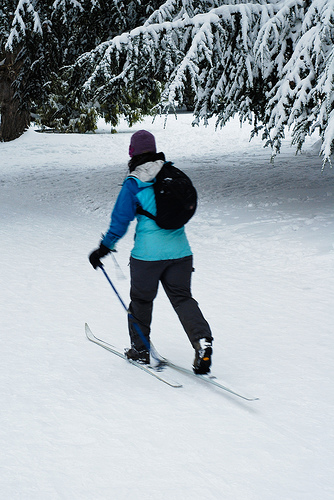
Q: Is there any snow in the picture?
A: Yes, there is snow.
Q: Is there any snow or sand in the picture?
A: Yes, there is snow.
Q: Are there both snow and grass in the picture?
A: No, there is snow but no grass.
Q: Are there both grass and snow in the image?
A: No, there is snow but no grass.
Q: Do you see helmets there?
A: No, there are no helmets.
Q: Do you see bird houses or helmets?
A: No, there are no helmets or bird houses.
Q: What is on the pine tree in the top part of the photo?
A: The snow is on the pine.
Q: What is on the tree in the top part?
A: The snow is on the pine.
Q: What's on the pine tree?
A: The snow is on the pine.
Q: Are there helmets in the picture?
A: No, there are no helmets.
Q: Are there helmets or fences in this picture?
A: No, there are no helmets or fences.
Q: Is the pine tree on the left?
A: Yes, the pine tree is on the left of the image.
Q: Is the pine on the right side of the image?
A: No, the pine is on the left of the image.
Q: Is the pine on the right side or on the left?
A: The pine is on the left of the image.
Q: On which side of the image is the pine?
A: The pine is on the left of the image.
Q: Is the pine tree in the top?
A: Yes, the pine tree is in the top of the image.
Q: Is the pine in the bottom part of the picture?
A: No, the pine is in the top of the image.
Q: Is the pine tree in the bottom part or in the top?
A: The pine tree is in the top of the image.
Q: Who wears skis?
A: The skier wears skis.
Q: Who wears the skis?
A: The skier wears skis.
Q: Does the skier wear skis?
A: Yes, the skier wears skis.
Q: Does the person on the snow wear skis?
A: Yes, the skier wears skis.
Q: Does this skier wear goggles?
A: No, the skier wears skis.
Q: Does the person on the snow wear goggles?
A: No, the skier wears skis.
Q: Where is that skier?
A: The skier is on the snow.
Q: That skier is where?
A: The skier is on the snow.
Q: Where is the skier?
A: The skier is on the snow.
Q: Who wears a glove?
A: The skier wears a glove.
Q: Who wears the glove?
A: The skier wears a glove.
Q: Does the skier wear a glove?
A: Yes, the skier wears a glove.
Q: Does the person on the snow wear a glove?
A: Yes, the skier wears a glove.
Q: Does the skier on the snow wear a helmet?
A: No, the skier wears a glove.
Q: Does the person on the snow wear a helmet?
A: No, the skier wears a glove.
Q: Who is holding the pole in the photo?
A: The skier is holding the pole.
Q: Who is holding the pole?
A: The skier is holding the pole.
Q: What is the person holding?
A: The skier is holding the pole.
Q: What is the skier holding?
A: The skier is holding the pole.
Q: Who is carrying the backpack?
A: The skier is carrying the backpack.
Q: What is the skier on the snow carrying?
A: The skier is carrying a backpack.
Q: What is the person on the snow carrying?
A: The skier is carrying a backpack.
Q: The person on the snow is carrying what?
A: The skier is carrying a backpack.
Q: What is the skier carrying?
A: The skier is carrying a backpack.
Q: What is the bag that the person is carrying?
A: The bag is a backpack.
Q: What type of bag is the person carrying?
A: The skier is carrying a backpack.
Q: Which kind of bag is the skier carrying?
A: The skier is carrying a backpack.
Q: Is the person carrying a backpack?
A: Yes, the skier is carrying a backpack.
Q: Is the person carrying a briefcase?
A: No, the skier is carrying a backpack.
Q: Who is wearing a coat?
A: The skier is wearing a coat.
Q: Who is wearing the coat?
A: The skier is wearing a coat.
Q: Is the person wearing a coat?
A: Yes, the skier is wearing a coat.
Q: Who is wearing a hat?
A: The skier is wearing a hat.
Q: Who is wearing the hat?
A: The skier is wearing a hat.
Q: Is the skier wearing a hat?
A: Yes, the skier is wearing a hat.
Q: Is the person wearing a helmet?
A: No, the skier is wearing a hat.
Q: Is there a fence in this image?
A: No, there are no fences.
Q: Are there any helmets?
A: No, there are no helmets.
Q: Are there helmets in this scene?
A: No, there are no helmets.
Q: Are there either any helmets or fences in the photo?
A: No, there are no helmets or fences.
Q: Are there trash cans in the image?
A: No, there are no trash cans.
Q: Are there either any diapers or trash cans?
A: No, there are no trash cans or diapers.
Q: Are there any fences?
A: No, there are no fences.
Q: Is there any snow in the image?
A: Yes, there is snow.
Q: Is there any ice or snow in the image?
A: Yes, there is snow.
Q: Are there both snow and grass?
A: No, there is snow but no grass.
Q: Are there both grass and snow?
A: No, there is snow but no grass.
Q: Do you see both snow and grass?
A: No, there is snow but no grass.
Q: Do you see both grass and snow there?
A: No, there is snow but no grass.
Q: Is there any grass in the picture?
A: No, there is no grass.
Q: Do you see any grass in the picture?
A: No, there is no grass.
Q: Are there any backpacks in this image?
A: Yes, there is a backpack.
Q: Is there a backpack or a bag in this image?
A: Yes, there is a backpack.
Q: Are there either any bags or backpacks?
A: Yes, there is a backpack.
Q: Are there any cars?
A: No, there are no cars.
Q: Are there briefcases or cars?
A: No, there are no cars or briefcases.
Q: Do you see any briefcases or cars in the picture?
A: No, there are no cars or briefcases.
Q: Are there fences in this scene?
A: No, there are no fences.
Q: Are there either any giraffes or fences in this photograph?
A: No, there are no fences or giraffes.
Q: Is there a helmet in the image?
A: No, there are no helmets.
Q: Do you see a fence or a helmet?
A: No, there are no helmets or fences.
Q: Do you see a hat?
A: Yes, there is a hat.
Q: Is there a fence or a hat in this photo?
A: Yes, there is a hat.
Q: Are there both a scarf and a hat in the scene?
A: No, there is a hat but no scarves.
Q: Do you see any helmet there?
A: No, there are no helmets.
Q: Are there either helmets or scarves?
A: No, there are no helmets or scarves.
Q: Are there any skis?
A: Yes, there are skis.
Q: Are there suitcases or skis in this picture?
A: Yes, there are skis.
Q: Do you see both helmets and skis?
A: No, there are skis but no helmets.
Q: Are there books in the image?
A: No, there are no books.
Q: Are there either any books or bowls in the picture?
A: No, there are no books or bowls.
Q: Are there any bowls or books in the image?
A: No, there are no books or bowls.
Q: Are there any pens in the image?
A: No, there are no pens.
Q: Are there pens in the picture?
A: No, there are no pens.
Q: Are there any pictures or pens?
A: No, there are no pens or pictures.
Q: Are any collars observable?
A: Yes, there is a collar.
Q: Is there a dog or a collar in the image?
A: Yes, there is a collar.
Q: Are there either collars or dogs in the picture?
A: Yes, there is a collar.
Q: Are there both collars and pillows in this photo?
A: No, there is a collar but no pillows.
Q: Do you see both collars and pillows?
A: No, there is a collar but no pillows.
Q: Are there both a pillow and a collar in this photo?
A: No, there is a collar but no pillows.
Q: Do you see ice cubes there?
A: No, there are no ice cubes.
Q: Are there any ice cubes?
A: No, there are no ice cubes.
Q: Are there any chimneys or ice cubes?
A: No, there are no ice cubes or chimneys.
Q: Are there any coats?
A: Yes, there is a coat.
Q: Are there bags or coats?
A: Yes, there is a coat.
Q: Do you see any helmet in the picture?
A: No, there are no helmets.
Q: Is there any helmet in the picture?
A: No, there are no helmets.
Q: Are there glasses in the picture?
A: No, there are no glasses.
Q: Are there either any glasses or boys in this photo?
A: No, there are no glasses or boys.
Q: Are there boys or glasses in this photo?
A: No, there are no glasses or boys.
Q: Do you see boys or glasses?
A: No, there are no glasses or boys.